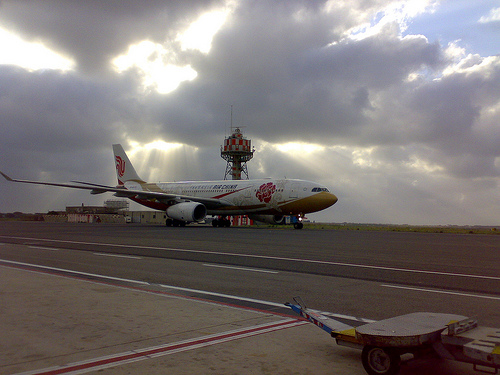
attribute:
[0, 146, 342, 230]
plane — a jet, parked, white, gold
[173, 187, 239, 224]
engine — for jet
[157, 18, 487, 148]
clouds — dark, stormy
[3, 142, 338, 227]
jet — large, passenger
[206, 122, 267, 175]
tower — pattern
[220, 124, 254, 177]
tower — orange, white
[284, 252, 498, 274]
runway — for jet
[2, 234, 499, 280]
strip marking — white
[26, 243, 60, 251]
strip marking — white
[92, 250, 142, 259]
strip marking — white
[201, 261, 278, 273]
strip marking — white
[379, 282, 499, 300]
strip marking — white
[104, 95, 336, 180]
sunlight — beaming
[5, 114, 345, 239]
jet — passenger, parked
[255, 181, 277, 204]
brand — airline name